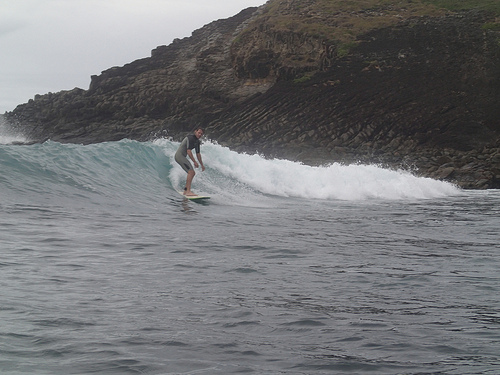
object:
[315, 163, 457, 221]
wave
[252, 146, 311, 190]
wave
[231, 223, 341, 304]
water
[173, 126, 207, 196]
man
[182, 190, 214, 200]
surfboard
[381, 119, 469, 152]
rocks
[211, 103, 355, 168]
shore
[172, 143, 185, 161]
bent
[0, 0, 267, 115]
sky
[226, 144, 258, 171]
crest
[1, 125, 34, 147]
water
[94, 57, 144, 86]
ridge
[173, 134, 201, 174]
wet suit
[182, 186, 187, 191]
leg strap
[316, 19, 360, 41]
grass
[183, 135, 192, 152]
sleeves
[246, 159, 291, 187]
foam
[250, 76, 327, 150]
rock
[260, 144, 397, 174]
seaside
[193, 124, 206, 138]
head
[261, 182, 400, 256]
ocean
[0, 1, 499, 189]
mountain